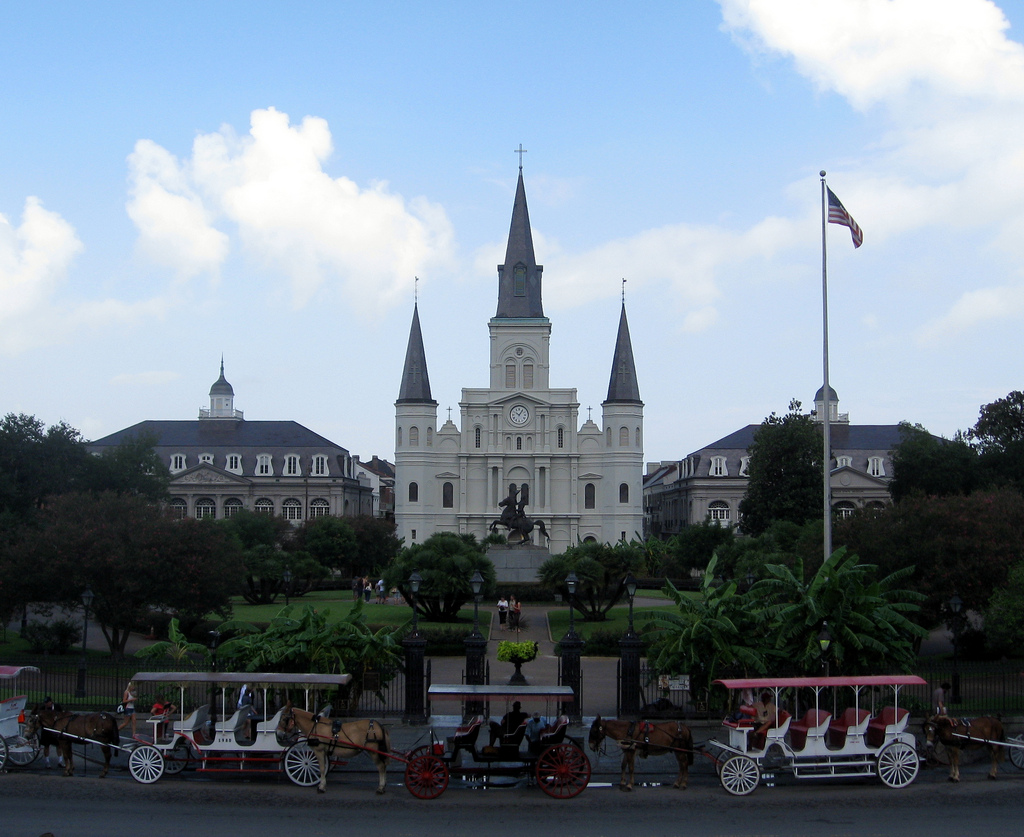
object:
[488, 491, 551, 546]
statue